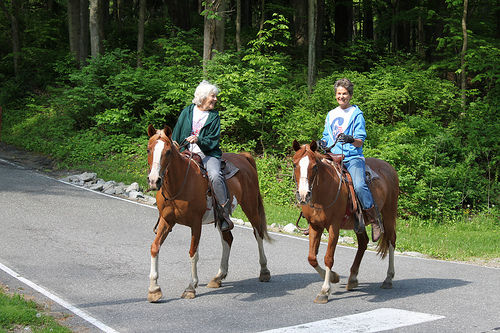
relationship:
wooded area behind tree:
[5, 3, 497, 141] [56, 50, 156, 135]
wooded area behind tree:
[5, 3, 497, 141] [136, 40, 299, 156]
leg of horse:
[310, 222, 343, 305] [291, 138, 398, 303]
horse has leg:
[141, 127, 273, 303] [209, 213, 232, 292]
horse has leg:
[141, 127, 273, 303] [244, 206, 272, 279]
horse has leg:
[291, 138, 398, 303] [345, 223, 371, 292]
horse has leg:
[291, 138, 398, 303] [375, 220, 397, 289]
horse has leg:
[291, 138, 398, 303] [303, 228, 342, 282]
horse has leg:
[291, 138, 398, 303] [313, 224, 341, 304]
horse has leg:
[141, 127, 273, 303] [243, 200, 271, 282]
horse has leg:
[141, 127, 273, 303] [207, 219, 237, 280]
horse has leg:
[141, 127, 273, 303] [179, 222, 202, 301]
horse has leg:
[141, 127, 273, 303] [146, 217, 173, 302]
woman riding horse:
[319, 78, 385, 242] [291, 138, 398, 303]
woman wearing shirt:
[319, 78, 385, 242] [321, 107, 365, 157]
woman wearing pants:
[319, 78, 385, 242] [338, 153, 372, 210]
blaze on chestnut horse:
[145, 137, 166, 180] [146, 123, 277, 302]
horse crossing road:
[128, 164, 305, 239] [0, 147, 499, 327]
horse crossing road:
[291, 138, 398, 303] [0, 147, 499, 327]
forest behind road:
[1, 0, 498, 264] [0, 147, 499, 327]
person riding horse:
[319, 77, 385, 242] [291, 138, 398, 303]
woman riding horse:
[168, 77, 236, 232] [141, 127, 273, 303]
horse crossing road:
[141, 127, 273, 303] [0, 147, 499, 327]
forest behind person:
[1, 0, 498, 264] [319, 77, 385, 242]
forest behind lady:
[1, 0, 498, 264] [166, 79, 235, 232]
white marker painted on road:
[333, 306, 410, 331] [13, 185, 391, 310]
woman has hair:
[168, 77, 236, 232] [192, 80, 219, 108]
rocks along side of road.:
[59, 170, 158, 206] [0, 144, 321, 331]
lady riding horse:
[166, 79, 235, 232] [141, 127, 273, 303]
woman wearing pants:
[168, 77, 236, 232] [193, 153, 226, 210]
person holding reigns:
[319, 77, 385, 242] [322, 128, 349, 205]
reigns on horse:
[322, 128, 349, 205] [284, 135, 401, 303]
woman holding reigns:
[168, 77, 236, 232] [171, 135, 195, 205]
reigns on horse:
[171, 135, 195, 205] [141, 127, 273, 303]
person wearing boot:
[319, 77, 385, 242] [364, 201, 383, 241]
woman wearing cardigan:
[165, 75, 239, 235] [168, 102, 226, 157]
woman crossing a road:
[326, 77, 376, 287] [0, 147, 499, 327]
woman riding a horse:
[326, 77, 376, 287] [290, 147, 410, 299]